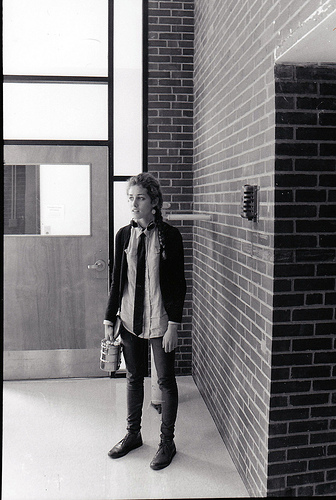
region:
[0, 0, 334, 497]
the picture is black and white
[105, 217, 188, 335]
the girl is wearing a jacket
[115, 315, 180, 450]
the girl is wearing jeans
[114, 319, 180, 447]
the girl's jeans are skinny jeans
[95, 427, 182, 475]
the girl is wearing lace up boots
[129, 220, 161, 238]
the girl is wearing a shirt with a collar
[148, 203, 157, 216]
the girl is wearing earrings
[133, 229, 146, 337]
the girl is wearing a tie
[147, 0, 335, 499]
the wall is brick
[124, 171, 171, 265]
the girl has a braid in her hair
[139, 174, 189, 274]
Person has long braid.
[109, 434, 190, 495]
Person wearing dark shoes.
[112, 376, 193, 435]
Person wearing black pants.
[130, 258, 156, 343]
Person wearing black tie.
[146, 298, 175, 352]
Person wearing button down shirt.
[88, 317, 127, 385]
Person holding silver object.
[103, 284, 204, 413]
Person standing near brick wall.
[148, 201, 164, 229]
Large earrings on person's ears.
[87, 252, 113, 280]
Silver door handle on door.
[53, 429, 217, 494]
Floor is white in color.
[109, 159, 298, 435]
a woman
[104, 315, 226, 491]
a woman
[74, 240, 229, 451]
a woman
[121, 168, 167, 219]
the head of a woman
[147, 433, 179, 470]
a black shoe on the woman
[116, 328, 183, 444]
a pair of pants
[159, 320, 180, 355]
the hand of a woman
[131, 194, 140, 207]
the nose of a woman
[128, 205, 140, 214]
the mouth of a woman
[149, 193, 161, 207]
the ear of a woman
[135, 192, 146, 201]
the eye of a woman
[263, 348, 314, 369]
a brick in the wall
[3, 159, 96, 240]
a window on the door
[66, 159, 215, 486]
this picture is black and white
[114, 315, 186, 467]
woman wearing skinny jeans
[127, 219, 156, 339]
woman wearing a tie traditionally worn by men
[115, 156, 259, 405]
woman standing beside a brick wall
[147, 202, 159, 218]
woman wearing oval shaped earrings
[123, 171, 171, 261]
woman wearing her hair in a braid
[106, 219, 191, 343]
woman's shirt is not tucked into her waistband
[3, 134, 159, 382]
woman standing near a door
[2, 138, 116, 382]
this door has a glass window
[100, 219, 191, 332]
woman is wearing a sweater